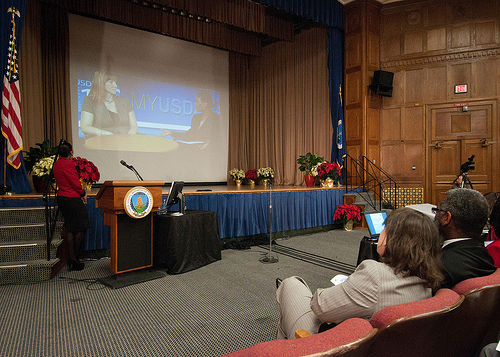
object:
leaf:
[301, 155, 306, 160]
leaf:
[300, 161, 306, 164]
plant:
[298, 150, 323, 186]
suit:
[275, 257, 432, 341]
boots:
[68, 253, 86, 271]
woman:
[52, 141, 92, 273]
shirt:
[53, 153, 89, 200]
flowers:
[79, 171, 91, 181]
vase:
[79, 178, 91, 192]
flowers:
[232, 170, 236, 176]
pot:
[234, 178, 246, 186]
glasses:
[431, 204, 453, 216]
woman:
[269, 207, 448, 341]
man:
[426, 187, 498, 299]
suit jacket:
[431, 238, 498, 295]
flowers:
[357, 214, 361, 223]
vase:
[343, 218, 357, 230]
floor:
[0, 228, 412, 355]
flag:
[1, 0, 35, 194]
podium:
[89, 174, 169, 291]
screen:
[64, 13, 239, 186]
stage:
[0, 153, 396, 287]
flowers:
[339, 209, 347, 216]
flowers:
[310, 169, 319, 177]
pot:
[321, 179, 336, 189]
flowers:
[299, 154, 307, 162]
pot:
[303, 175, 318, 186]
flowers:
[261, 167, 267, 173]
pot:
[260, 178, 272, 185]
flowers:
[250, 172, 252, 176]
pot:
[249, 179, 257, 188]